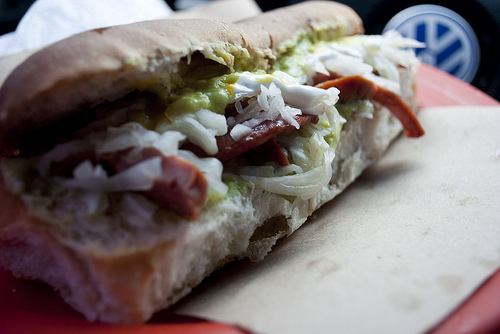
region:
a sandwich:
[5, 22, 432, 279]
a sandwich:
[40, 11, 433, 288]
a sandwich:
[39, 10, 460, 273]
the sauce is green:
[170, 76, 234, 136]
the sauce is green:
[175, 64, 242, 124]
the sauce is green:
[172, 58, 229, 116]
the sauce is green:
[165, 59, 233, 119]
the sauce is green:
[174, 60, 236, 113]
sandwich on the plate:
[1, 28, 355, 302]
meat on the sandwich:
[154, 164, 201, 211]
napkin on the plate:
[361, 230, 426, 265]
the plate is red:
[424, 78, 470, 103]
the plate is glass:
[440, 77, 488, 99]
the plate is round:
[460, 306, 497, 327]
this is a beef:
[237, 120, 280, 153]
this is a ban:
[120, 22, 195, 64]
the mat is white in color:
[378, 206, 473, 278]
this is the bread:
[35, 51, 92, 81]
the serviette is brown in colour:
[324, 257, 406, 309]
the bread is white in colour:
[186, 232, 223, 260]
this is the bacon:
[220, 142, 257, 154]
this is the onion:
[287, 156, 312, 190]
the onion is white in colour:
[267, 177, 317, 194]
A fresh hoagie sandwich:
[9, 4, 439, 294]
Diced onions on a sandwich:
[242, 79, 305, 136]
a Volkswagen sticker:
[384, 2, 481, 81]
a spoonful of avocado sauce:
[170, 71, 243, 118]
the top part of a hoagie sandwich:
[4, 4, 372, 78]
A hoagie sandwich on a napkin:
[17, 3, 496, 307]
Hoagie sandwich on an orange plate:
[7, 4, 494, 319]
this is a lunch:
[62, 32, 414, 295]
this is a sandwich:
[34, 22, 464, 265]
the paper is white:
[299, 173, 429, 324]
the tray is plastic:
[133, 293, 226, 332]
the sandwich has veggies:
[71, 80, 298, 220]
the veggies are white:
[83, 130, 194, 238]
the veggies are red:
[143, 77, 290, 245]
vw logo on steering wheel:
[381, 4, 480, 84]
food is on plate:
[1, 4, 421, 326]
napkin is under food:
[1, 0, 498, 332]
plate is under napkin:
[1, 62, 498, 331]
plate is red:
[0, 64, 498, 332]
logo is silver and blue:
[380, 3, 480, 83]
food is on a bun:
[0, 1, 417, 320]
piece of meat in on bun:
[98, 141, 210, 218]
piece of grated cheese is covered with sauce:
[152, 115, 215, 150]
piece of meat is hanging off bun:
[321, 71, 423, 138]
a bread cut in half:
[43, 2, 469, 289]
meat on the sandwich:
[219, 105, 348, 200]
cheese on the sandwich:
[165, 93, 237, 164]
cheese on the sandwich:
[226, 78, 293, 134]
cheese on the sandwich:
[291, 83, 347, 153]